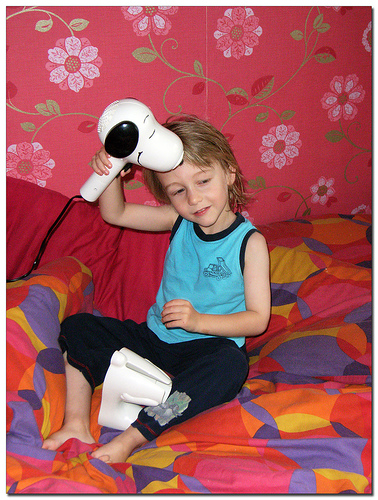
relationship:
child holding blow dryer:
[45, 115, 271, 466] [79, 97, 182, 206]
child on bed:
[45, 115, 271, 466] [7, 177, 370, 496]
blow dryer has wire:
[79, 97, 182, 206] [11, 195, 80, 283]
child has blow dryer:
[45, 115, 271, 466] [79, 97, 182, 206]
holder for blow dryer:
[98, 347, 171, 432] [79, 97, 182, 206]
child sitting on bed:
[45, 115, 271, 466] [7, 177, 370, 496]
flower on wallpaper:
[45, 36, 103, 95] [7, 6, 373, 228]